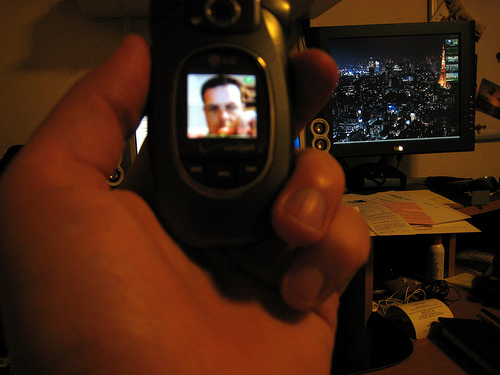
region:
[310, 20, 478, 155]
part of a black flat t.v.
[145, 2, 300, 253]
a small black cellphone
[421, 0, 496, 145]
part of a gray board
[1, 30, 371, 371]
the hand of a person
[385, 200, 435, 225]
a pink piece of paper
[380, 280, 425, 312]
a white cord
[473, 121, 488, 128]
a small board tac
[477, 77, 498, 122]
part of a picture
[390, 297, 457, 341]
a white receipt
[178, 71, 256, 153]
face on the phone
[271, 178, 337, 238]
fingernail on the phone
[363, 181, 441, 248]
papers in the background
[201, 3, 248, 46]
circle on the camera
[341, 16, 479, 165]
television turned on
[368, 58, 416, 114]
picture of a city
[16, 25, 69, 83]
wall in the background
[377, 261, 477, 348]
stuff on the floor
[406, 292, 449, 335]
paper on the floor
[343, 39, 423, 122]
lights of the city on the television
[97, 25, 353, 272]
The person is taking a selfie.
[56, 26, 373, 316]
The person is holding a cellphone.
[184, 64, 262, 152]
A picture of the person is in the cell phone.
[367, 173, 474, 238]
Scattered papers on the table.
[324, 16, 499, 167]
The flat screen tv is on.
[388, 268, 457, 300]
Cords are under the table.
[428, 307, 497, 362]
A book is on the floor.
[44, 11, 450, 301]
It is dark in the room.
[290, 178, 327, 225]
The fingernails on a person finger.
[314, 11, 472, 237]
the television is sitting on stand.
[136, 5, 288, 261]
a closed flip phone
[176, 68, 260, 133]
a picture on a cell phone screen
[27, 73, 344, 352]
a person's left hand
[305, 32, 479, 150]
a flat screen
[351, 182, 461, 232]
a stack of papers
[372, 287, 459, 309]
a tangle of wires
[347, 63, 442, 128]
a photo of a cityscape at night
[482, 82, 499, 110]
a postcard on a wall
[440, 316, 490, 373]
a black book on the floor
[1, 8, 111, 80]
a stretch of blank wall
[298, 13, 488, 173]
view finder of a camcorder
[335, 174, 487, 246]
stack of papers on a table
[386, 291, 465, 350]
receipt on a table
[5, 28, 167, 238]
thumb of a person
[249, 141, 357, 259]
finger of a person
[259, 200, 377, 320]
finger of a person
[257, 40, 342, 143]
finger of a person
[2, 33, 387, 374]
hand of a person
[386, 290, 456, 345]
white receipt with black writing